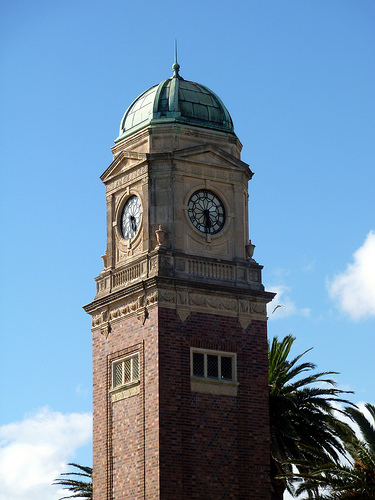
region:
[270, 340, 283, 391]
Large green leaf on palm tree.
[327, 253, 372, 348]
White cloud in sky.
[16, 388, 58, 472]
White cloud in sky.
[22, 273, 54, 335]
Sky is blue and clear.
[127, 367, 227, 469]
Brick tower in front of trees.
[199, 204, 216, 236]
Black hands on clock.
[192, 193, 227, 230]
Black numbers on clock.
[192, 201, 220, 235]
Numbers on clock are roman numeral.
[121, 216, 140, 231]
Hands on clock are black.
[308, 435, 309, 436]
edge of a leaf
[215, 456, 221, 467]
part of a wall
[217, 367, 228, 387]
part of a window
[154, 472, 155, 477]
edge of a wall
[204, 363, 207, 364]
side of a window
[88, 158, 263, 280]
a clock on a building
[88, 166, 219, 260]
a large clock on a building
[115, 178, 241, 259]
an outside clock on a building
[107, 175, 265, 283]
a large otuside clock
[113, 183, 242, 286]
an outside large clock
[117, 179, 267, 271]
a large outside clock on building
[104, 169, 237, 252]
a building with clock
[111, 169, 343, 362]
a building with outside clock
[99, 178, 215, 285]
a building with large outside clock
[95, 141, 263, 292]
an ornate looking clock tower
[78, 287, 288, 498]
the body of the tower is made of brick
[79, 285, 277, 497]
the bricks are different colors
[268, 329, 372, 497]
palm trees behind the clock tower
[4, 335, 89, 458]
the day is partly cloudy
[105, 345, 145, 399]
windows set into the clock tower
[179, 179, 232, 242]
the time on the clock is 5:30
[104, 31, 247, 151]
the roof of the clock tower has a green patina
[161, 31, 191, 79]
spire at the top of the clock tower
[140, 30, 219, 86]
the top of a castle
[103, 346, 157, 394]
the window of a castle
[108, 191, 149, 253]
a round decoration on the wall of a castle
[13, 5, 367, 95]
the blue sky over the castle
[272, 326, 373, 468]
green leaves of a tree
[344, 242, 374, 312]
white clouds on the sky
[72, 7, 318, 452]
a tall castle building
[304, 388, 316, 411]
green leaves on the tree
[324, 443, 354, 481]
green leaves on the tree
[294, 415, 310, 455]
green leaves on the tree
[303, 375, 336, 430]
green leaves on the tree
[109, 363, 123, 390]
a window on a building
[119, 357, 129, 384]
a window on a building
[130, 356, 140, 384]
a window on a building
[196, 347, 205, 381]
a window on a building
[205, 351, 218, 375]
a window on a building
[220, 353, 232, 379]
a window on a building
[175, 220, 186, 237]
a stone in a wall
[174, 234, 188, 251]
a stone in a wall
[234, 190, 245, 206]
a stone in a wall